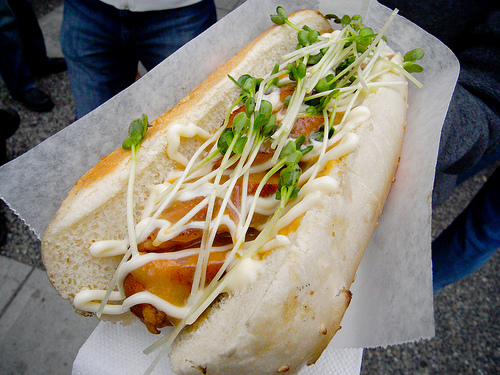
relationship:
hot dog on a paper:
[36, 9, 408, 375] [3, 0, 460, 350]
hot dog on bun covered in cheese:
[36, 0, 426, 372] [127, 0, 424, 237]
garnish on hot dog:
[120, 112, 153, 263] [36, 0, 426, 372]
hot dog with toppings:
[36, 9, 408, 375] [220, 65, 324, 181]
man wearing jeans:
[54, 0, 214, 96] [64, 7, 159, 127]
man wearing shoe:
[1, 0, 60, 116] [2, 76, 57, 116]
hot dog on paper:
[36, 9, 408, 375] [3, 0, 460, 350]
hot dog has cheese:
[36, 9, 408, 375] [134, 266, 187, 291]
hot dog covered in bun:
[36, 9, 408, 375] [162, 39, 410, 375]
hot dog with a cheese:
[36, 9, 408, 375] [131, 251, 229, 305]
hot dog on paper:
[36, 0, 426, 372] [3, 0, 460, 350]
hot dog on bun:
[36, 0, 426, 372] [57, 9, 429, 371]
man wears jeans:
[56, 0, 218, 126] [57, 0, 223, 132]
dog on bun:
[120, 37, 370, 335] [40, 8, 407, 372]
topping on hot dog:
[264, 174, 336, 234] [36, 9, 408, 375]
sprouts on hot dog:
[324, 12, 381, 72] [120, 32, 355, 324]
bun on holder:
[37, 8, 334, 326] [325, 54, 463, 354]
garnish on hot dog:
[73, 6, 424, 371] [125, 86, 325, 335]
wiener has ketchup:
[106, 28, 400, 342] [234, 105, 258, 123]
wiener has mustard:
[106, 28, 400, 342] [307, 156, 334, 201]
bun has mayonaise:
[40, 8, 407, 372] [70, 105, 370, 318]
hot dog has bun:
[36, 9, 408, 375] [40, 8, 407, 372]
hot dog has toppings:
[36, 9, 408, 375] [303, 39, 350, 86]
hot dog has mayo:
[36, 9, 408, 375] [166, 120, 196, 156]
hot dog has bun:
[36, 9, 408, 375] [186, 322, 337, 367]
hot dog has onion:
[36, 9, 408, 375] [310, 69, 340, 108]